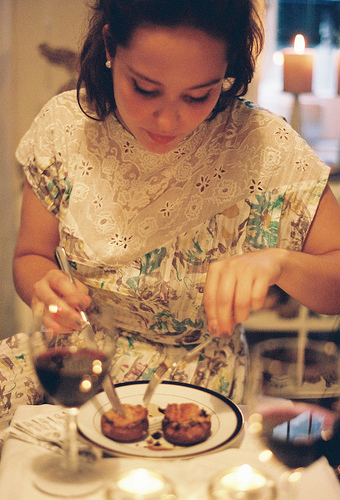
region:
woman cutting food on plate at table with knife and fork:
[2, 1, 332, 474]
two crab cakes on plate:
[100, 393, 211, 447]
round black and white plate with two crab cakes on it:
[64, 365, 250, 463]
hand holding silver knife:
[142, 246, 272, 410]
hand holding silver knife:
[29, 241, 134, 424]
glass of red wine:
[25, 279, 120, 497]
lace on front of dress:
[90, 146, 189, 231]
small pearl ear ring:
[101, 56, 113, 72]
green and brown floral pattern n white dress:
[127, 278, 193, 346]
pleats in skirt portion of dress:
[128, 346, 181, 380]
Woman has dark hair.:
[85, 46, 117, 125]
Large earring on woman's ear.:
[94, 56, 115, 74]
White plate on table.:
[87, 378, 225, 459]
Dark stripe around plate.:
[95, 360, 240, 467]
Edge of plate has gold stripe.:
[70, 393, 250, 452]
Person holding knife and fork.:
[103, 377, 171, 405]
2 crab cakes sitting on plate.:
[108, 395, 225, 448]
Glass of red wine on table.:
[34, 364, 118, 467]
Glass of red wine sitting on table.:
[265, 421, 316, 498]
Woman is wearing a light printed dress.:
[87, 211, 213, 384]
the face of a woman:
[114, 24, 221, 151]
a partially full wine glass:
[28, 297, 104, 499]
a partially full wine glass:
[247, 334, 339, 494]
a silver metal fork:
[143, 324, 216, 411]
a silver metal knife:
[51, 240, 138, 415]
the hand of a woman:
[31, 270, 92, 322]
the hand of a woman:
[206, 247, 288, 333]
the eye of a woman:
[132, 79, 158, 96]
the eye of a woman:
[185, 90, 208, 104]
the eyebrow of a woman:
[128, 63, 166, 88]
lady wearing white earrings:
[75, 6, 266, 169]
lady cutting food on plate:
[71, 11, 321, 442]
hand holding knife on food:
[6, 243, 129, 428]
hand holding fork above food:
[114, 282, 277, 433]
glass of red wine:
[5, 296, 102, 499]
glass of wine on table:
[23, 327, 116, 488]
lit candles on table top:
[92, 450, 303, 498]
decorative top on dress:
[14, 17, 279, 399]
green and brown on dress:
[36, 176, 214, 349]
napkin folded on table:
[13, 393, 142, 493]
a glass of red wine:
[29, 295, 109, 495]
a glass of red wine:
[250, 338, 338, 498]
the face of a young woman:
[100, 0, 243, 154]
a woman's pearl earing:
[105, 60, 112, 68]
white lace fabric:
[75, 155, 217, 214]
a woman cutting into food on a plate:
[0, 0, 339, 460]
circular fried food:
[159, 401, 212, 444]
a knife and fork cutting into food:
[99, 384, 155, 438]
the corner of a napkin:
[4, 411, 64, 445]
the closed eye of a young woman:
[128, 75, 162, 98]